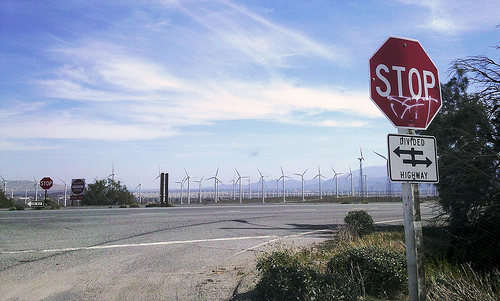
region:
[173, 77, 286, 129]
cloud in the sky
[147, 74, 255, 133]
the cloud is white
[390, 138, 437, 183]
a sign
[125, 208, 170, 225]
the street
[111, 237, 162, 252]
a white line in the street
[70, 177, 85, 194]
a red and white sign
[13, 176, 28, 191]
a mountain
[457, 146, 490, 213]
the green bush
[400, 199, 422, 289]
a metal pole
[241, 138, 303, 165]
the sky is clear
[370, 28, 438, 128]
red and white stop sign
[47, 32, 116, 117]
white clouds in blue sky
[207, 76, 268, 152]
white clouds in blue sky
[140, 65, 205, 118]
white clouds in blue sky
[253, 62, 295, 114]
white clouds in blue sky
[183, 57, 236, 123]
white clouds in blue sky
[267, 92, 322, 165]
white clouds in blue sky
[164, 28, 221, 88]
white clouds in blue sky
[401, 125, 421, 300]
gray metal pole supporting a re stop sign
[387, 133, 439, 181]
white sign below stop sign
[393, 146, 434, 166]
black arrows printed on sign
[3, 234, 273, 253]
white line painted on road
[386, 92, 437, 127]
graffiti painted on stop sign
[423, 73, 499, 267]
green bush behind stop sign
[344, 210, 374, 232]
small bush next to road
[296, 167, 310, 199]
wind turbine next to wind turbine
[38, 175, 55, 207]
stop sign across road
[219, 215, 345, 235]
shadow on top of road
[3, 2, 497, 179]
thin clouds in sky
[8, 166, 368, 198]
wind turbines in field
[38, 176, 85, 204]
two signs on poles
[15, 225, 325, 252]
white line on road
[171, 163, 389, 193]
hazy mountains on horizon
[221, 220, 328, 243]
shadows on paved surface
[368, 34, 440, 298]
two signs on pole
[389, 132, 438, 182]
sign with two arrows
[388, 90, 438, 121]
spray paint on sign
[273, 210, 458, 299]
bushes on street corner